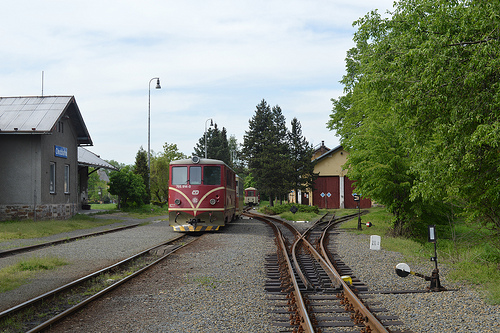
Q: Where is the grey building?
A: Train's left.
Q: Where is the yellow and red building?
A: Train's right.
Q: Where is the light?
A: On tall pole.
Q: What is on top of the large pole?
A: Light.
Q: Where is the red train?
A: Left track.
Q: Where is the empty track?
A: On right.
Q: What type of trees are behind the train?
A: Pine trees.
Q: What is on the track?
A: A red train.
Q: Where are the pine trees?
A: Behind the train.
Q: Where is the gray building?
A: To the left of the tracks.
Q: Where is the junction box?
A: To the right of the tracks.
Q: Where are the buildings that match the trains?
A: Behind the pine trees.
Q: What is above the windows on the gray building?
A: A blue sign.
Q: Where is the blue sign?
A: On the gray building.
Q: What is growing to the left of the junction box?
A: Trees.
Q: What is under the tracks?
A: Gravel.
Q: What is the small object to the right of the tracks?
A: Junction box.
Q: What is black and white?
A: The train track switch.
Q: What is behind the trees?
A: A tan and red building.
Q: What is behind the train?
A: Green pine trees.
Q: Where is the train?
A: On the tracks.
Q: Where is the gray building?
A: Beside the track.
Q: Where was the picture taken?
A: A train yard.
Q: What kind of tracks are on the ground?
A: Train tracks.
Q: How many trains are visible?
A: Two.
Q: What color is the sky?
A: Blue.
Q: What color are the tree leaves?
A: Green.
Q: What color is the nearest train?
A: Red.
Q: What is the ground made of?
A: Gravel.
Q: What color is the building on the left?
A: Gray.